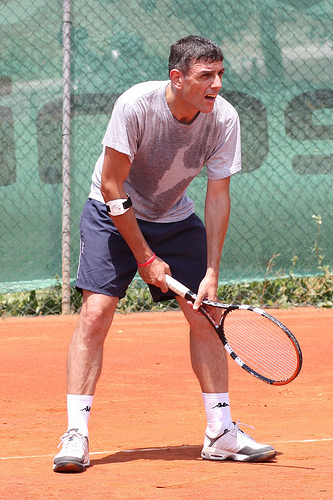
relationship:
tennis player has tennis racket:
[53, 30, 277, 476] [154, 271, 305, 390]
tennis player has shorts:
[53, 30, 277, 476] [76, 197, 216, 304]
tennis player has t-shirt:
[53, 30, 277, 476] [90, 81, 243, 224]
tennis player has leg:
[53, 30, 277, 476] [66, 196, 143, 451]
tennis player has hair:
[53, 30, 277, 476] [166, 36, 221, 76]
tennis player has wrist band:
[53, 30, 277, 476] [102, 191, 133, 220]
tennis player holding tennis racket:
[53, 30, 277, 476] [154, 271, 305, 390]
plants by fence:
[2, 274, 332, 311] [1, 0, 331, 308]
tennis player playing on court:
[53, 30, 277, 476] [1, 306, 326, 500]